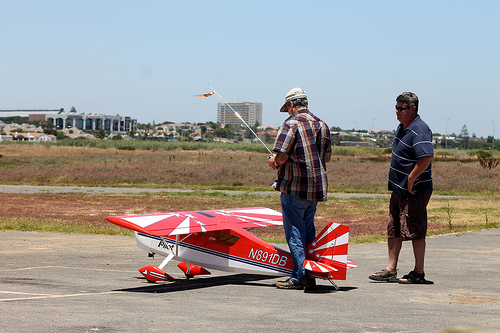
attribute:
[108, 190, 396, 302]
airplane — toy, red, white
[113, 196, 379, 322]
airplane — toy, blue, striped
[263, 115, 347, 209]
shirt — plaid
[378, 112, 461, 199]
shirt — striped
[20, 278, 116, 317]
lines — faded, painted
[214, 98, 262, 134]
building — tall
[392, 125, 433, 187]
shirt — blue, white, stripped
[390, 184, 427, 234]
pants — brown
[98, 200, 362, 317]
aircraft — red,  white 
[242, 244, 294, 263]
letters — white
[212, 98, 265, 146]
high rise — tall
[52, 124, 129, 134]
building —  white 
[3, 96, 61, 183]
building —  white 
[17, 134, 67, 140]
roof — orange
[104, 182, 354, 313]
plane — small , red, white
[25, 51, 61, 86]
clouds — white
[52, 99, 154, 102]
sky — blue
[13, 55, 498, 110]
sky — blue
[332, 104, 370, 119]
clouds — white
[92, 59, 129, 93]
clouds — white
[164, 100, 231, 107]
sky — blue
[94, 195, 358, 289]
airplane — red,  white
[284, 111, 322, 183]
shirt — checkered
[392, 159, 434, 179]
shirt — striped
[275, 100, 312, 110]
cap — white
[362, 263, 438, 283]
shoes — brown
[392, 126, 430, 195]
shirt — blue, white, stripes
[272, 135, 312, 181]
shirt — blue, white, yellow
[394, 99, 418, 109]
hair — dark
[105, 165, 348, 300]
plane — red, white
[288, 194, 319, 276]
jeans — blue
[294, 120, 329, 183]
shirt — plaid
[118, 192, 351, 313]
plane — red,  white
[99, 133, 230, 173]
grass — brown, green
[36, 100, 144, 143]
building — white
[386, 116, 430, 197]
shirt — blue